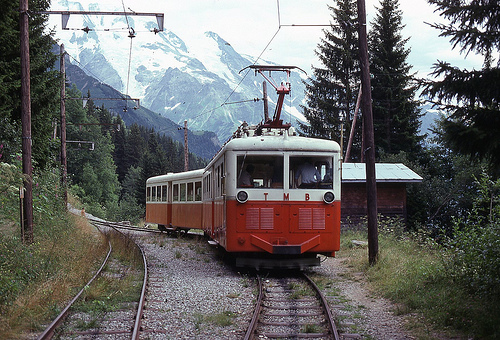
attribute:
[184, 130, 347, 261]
train — red, white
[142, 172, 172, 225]
car — last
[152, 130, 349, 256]
train — old, white, red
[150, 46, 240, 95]
mountain — snow-covered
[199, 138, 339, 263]
train — old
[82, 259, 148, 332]
train track — grass covered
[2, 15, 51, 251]
electrical pole — wooden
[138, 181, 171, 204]
window — square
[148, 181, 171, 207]
window — square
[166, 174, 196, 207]
window — square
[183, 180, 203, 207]
window — square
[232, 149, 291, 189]
window — square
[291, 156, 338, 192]
window — square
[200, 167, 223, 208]
window — square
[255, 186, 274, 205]
letter — T , on the front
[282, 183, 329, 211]
letter — on the front, B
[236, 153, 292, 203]
window — left front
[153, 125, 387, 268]
train — right front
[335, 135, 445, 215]
building — on the right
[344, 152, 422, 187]
roof — white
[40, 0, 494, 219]
mountain — in the background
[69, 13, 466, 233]
mountains — in the background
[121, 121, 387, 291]
train — white, orange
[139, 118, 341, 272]
train — red and white, red, white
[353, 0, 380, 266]
pole — wooden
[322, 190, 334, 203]
light — round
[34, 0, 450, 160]
mountain — white, snowy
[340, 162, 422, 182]
roof — white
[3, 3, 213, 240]
fir trees — Tall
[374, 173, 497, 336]
bushes — Green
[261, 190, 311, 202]
letters — red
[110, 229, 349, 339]
rocks — small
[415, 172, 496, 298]
bush — green